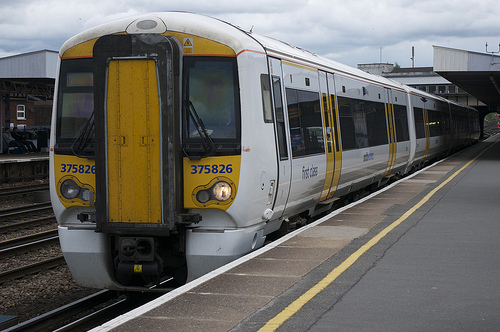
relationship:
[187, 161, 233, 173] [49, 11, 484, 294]
number on large train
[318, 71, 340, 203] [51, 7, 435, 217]
doors on train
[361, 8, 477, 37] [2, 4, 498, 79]
cloud in sky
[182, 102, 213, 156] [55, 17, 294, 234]
wiper on train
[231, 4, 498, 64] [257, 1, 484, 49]
clouds in sky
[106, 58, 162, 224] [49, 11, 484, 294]
door on large train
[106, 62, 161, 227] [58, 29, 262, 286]
door on end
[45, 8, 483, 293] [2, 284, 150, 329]
large train on train track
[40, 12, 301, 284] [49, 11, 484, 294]
lead car on large train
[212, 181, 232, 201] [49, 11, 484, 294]
light on large train